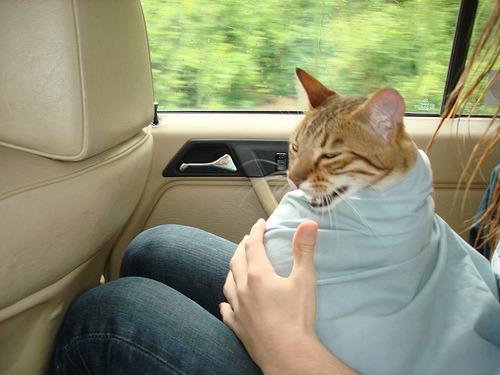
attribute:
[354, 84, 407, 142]
ear — pink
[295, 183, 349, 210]
mouth — open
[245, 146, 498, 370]
blanket — blue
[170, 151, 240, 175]
handle — door, silver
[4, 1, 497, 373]
interior — cream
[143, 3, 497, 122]
trees — green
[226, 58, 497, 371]
cat — brown, white, striped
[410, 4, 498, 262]
hair — brown, long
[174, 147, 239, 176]
handle — door, silver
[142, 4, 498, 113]
foliage — blurred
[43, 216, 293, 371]
jeans — blue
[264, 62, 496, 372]
cat — brown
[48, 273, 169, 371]
knee — bent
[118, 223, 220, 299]
knee — bent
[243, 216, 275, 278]
finger — curled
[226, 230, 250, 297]
finger — curled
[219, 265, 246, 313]
finger — curled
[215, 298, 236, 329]
finger — curled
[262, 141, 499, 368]
fabric — blue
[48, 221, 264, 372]
jeans — blue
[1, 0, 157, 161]
headrest — brown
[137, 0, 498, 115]
window — car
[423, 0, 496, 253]
hair — blonde, light brown, long, brown